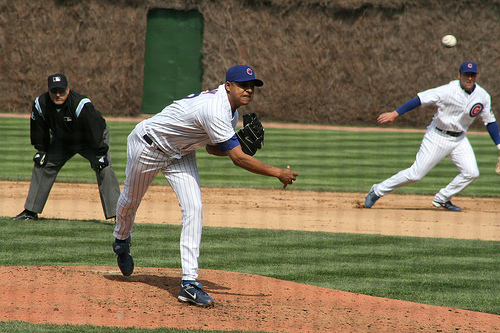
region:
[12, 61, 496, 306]
three baseball players on baseball field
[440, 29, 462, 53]
small white baseball ball on air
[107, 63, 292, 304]
pitcher wearing blue and white uniform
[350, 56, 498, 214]
baseball player on right camp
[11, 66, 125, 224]
umpier wearing black jacket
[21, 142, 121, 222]
gray pants of umpier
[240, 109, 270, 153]
black glove of pitcher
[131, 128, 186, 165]
black belt of pitcher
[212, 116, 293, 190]
right arm throwing ball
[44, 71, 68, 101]
black cap of umpier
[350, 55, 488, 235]
man wearing a cap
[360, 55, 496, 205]
man wearing white shirt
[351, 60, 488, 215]
man wearing white pants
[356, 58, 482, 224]
man wearing blue shoes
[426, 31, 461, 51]
ball up in the air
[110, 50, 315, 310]
man wearing blue cap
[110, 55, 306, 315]
man wearing white shirt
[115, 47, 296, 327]
man wearing white pants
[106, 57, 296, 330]
man holding a glove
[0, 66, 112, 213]
man wearing black cap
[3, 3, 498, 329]
people playing baseball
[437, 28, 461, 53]
ball of baseball in teh air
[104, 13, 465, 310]
catcher throwing a ball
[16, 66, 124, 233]
the umpire is bend forward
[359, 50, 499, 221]
baseball player is running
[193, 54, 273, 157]
player wears a blue cap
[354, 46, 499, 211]
player wears a white team uniform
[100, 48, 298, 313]
player wears a white team uniform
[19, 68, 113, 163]
man wears a black cup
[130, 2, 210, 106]
a green door on the background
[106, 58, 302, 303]
pitcher leaning forward with arm across body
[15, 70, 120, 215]
umpire leaning forward with hands on legs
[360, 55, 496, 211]
player leaning to one side on bent knees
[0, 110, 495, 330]
strips of lined grass between dirt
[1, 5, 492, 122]
rough texture of brown wall with green panel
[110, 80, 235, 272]
white uniform with thin stripes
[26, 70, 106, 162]
light blue stripes over shoulders of dark jacket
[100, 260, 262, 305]
shadow between two legs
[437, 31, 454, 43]
white ball with red curve floating in air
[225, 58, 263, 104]
blue cap shielding eyes with shade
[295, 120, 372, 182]
the lawn is green in colour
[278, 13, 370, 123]
the wall is brown in colour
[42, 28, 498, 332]
the men are playing baseball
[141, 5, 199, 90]
the door is green in colour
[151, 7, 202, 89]
the door is closed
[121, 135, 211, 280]
the pants are white in colour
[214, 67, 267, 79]
the hat is blue in colour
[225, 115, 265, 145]
the glove is in his hands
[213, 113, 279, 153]
the glove is black in colour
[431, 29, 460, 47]
the ball is white in colour